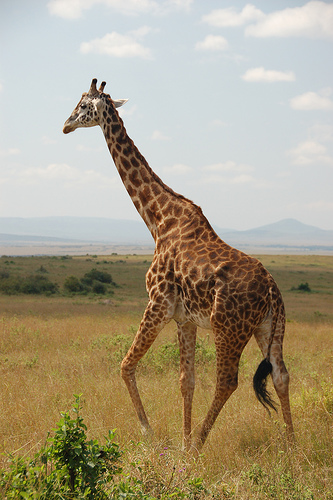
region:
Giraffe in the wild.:
[52, 73, 330, 469]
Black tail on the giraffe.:
[246, 343, 301, 413]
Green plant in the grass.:
[31, 394, 144, 498]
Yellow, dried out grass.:
[46, 331, 105, 424]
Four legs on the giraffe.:
[105, 301, 311, 477]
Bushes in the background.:
[26, 254, 126, 311]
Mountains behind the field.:
[34, 196, 128, 263]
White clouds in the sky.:
[201, 137, 293, 197]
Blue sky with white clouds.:
[195, 87, 332, 210]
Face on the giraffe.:
[46, 67, 154, 145]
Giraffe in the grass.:
[56, 77, 301, 467]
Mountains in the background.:
[225, 208, 329, 254]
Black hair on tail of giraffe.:
[251, 274, 286, 416]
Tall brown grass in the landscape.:
[62, 365, 120, 426]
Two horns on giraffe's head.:
[59, 68, 128, 139]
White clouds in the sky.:
[247, 5, 328, 44]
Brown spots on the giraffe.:
[65, 73, 207, 262]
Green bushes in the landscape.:
[17, 263, 120, 298]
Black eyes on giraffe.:
[58, 78, 122, 136]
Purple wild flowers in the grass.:
[147, 443, 207, 493]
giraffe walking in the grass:
[55, 70, 328, 474]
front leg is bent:
[97, 293, 175, 451]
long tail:
[250, 303, 299, 425]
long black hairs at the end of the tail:
[246, 355, 283, 419]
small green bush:
[2, 405, 151, 497]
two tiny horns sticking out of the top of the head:
[79, 74, 113, 93]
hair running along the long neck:
[113, 108, 214, 215]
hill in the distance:
[249, 210, 316, 236]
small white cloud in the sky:
[188, 33, 230, 56]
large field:
[3, 250, 329, 494]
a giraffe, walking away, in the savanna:
[51, 72, 297, 465]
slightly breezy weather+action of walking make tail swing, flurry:
[248, 285, 281, 424]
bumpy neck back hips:
[114, 108, 276, 301]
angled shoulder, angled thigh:
[137, 256, 255, 355]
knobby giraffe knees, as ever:
[115, 357, 303, 401]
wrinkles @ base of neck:
[173, 207, 209, 249]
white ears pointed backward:
[81, 93, 128, 110]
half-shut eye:
[75, 100, 88, 110]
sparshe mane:
[106, 97, 203, 217]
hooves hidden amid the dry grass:
[134, 418, 309, 476]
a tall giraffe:
[61, 77, 301, 458]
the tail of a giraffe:
[251, 284, 282, 416]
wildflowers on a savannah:
[155, 441, 185, 499]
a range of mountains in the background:
[0, 214, 332, 257]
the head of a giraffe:
[58, 76, 129, 134]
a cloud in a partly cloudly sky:
[241, 67, 296, 83]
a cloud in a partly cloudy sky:
[76, 28, 158, 62]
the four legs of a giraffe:
[117, 297, 300, 466]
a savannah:
[0, 254, 331, 490]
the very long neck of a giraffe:
[99, 115, 212, 248]